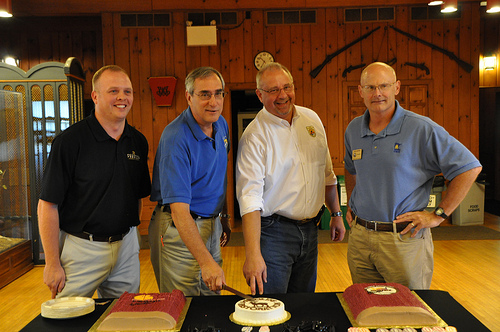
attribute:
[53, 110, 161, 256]
shirt — black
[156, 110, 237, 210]
shirt — blue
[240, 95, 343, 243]
shirt — white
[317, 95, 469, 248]
shirt — blue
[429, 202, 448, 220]
watch — black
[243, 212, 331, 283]
jeans — blue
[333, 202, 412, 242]
belt — brown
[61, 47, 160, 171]
man — blonde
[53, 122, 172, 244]
shirt — black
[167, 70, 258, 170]
man — grey haird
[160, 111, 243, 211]
shirt — blue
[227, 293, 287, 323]
cake — round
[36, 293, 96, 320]
plates — paper, stacked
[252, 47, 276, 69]
clock — round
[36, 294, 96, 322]
plates — stacked, white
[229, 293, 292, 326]
cake — small, circular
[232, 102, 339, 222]
shirt — white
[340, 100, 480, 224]
shirt — light blue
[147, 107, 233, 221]
shirt — bright blue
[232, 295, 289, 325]
cake — circular, white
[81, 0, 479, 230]
wall — wooden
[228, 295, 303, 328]
cake — white, small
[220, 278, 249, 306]
utensil — silver, knife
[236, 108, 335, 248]
shirt — white, man's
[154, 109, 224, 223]
shirt — man's, blue, polo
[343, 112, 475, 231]
shirt — polo, blue, man's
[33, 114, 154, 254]
shirt — man's, black, polo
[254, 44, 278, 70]
clock — wall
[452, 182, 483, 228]
can — lined, trash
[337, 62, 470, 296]
man — bald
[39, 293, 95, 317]
plates — paper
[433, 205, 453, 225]
watch — man's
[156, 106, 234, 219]
shirt — blue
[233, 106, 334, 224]
shirt — white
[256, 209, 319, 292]
jeans — blue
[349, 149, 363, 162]
tag — name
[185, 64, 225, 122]
face — man's